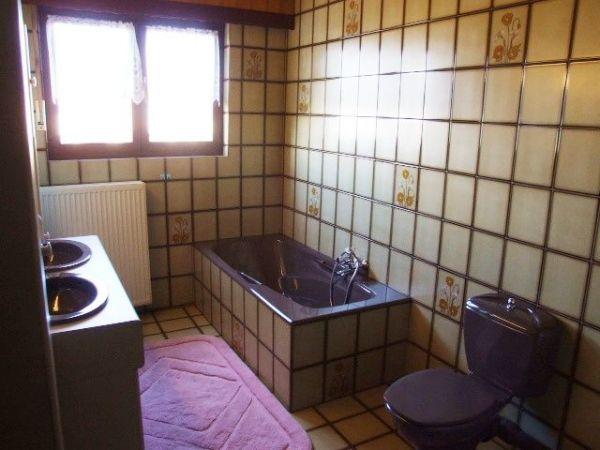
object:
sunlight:
[44, 15, 221, 145]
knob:
[30, 77, 37, 85]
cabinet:
[0, 0, 53, 345]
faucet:
[334, 247, 368, 276]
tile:
[352, 196, 371, 238]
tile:
[469, 232, 505, 289]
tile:
[477, 123, 516, 181]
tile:
[448, 122, 482, 175]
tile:
[554, 125, 600, 196]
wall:
[287, 0, 600, 450]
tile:
[523, 0, 575, 64]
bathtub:
[192, 233, 412, 414]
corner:
[191, 0, 407, 415]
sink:
[46, 273, 108, 322]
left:
[0, 2, 242, 447]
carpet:
[137, 334, 314, 449]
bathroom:
[0, 3, 598, 450]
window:
[41, 14, 218, 156]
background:
[25, 1, 287, 313]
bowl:
[382, 369, 514, 450]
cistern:
[464, 293, 559, 397]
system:
[383, 292, 566, 450]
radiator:
[36, 180, 153, 307]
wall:
[27, 2, 292, 309]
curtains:
[43, 12, 220, 109]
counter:
[40, 78, 145, 164]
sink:
[42, 240, 92, 273]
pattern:
[396, 167, 415, 208]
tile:
[393, 163, 420, 212]